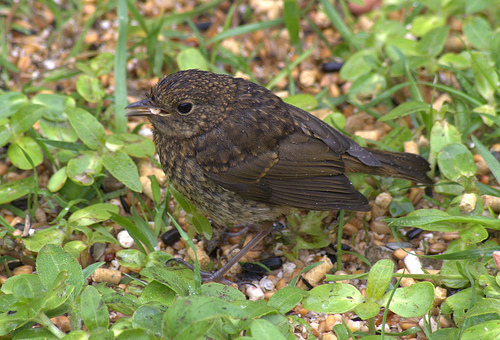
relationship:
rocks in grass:
[10, 21, 84, 108] [345, 23, 490, 87]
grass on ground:
[345, 23, 490, 87] [23, 22, 139, 328]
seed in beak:
[237, 252, 339, 300] [123, 87, 160, 124]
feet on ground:
[143, 257, 230, 290] [23, 22, 139, 328]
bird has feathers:
[127, 64, 365, 239] [177, 144, 261, 225]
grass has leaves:
[345, 23, 490, 87] [69, 101, 131, 179]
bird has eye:
[127, 64, 365, 239] [178, 95, 194, 116]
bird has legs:
[127, 64, 365, 239] [169, 223, 274, 278]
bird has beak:
[127, 64, 365, 239] [126, 87, 159, 124]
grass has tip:
[345, 23, 490, 87] [354, 42, 409, 113]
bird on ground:
[127, 64, 365, 239] [23, 22, 139, 328]